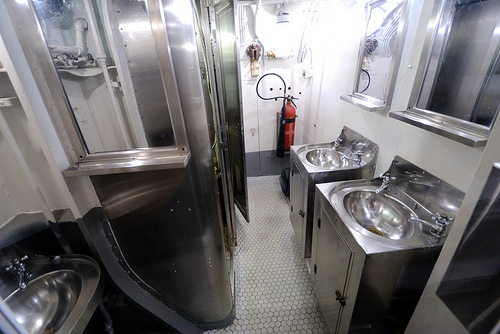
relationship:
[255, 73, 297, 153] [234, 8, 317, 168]
extinguisher against wall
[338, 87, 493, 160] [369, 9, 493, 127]
shelves in front of mirrors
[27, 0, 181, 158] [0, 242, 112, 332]
mirror to sink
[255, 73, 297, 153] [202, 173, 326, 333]
extinguisher on floor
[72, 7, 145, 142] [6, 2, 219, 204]
pipe reflected in mirror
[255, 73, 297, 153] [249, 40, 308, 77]
extinguisher under valves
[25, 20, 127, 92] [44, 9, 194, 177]
pipes in mirror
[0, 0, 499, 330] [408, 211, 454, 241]
bathroom has faucet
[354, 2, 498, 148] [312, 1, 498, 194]
mirrors on wall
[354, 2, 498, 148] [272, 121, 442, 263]
mirrors above sinks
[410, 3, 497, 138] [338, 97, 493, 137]
mirror with shelves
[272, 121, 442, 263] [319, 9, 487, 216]
sinks on wall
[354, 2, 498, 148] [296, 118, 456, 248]
mirrors above sinks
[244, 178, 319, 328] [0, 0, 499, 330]
floor in bathroom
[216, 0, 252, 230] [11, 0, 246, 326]
door on shower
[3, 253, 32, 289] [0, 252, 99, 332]
faucet on sink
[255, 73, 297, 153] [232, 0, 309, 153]
extinguisher on wall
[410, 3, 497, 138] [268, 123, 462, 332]
mirror above sinks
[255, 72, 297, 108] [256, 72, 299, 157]
co2 hose on extinguisher